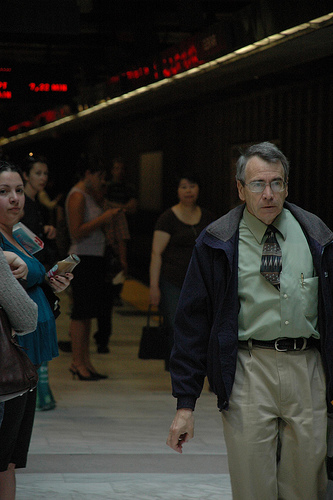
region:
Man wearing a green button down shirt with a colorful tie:
[178, 139, 330, 499]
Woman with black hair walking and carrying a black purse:
[137, 168, 201, 364]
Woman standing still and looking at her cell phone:
[62, 152, 129, 363]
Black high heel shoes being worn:
[63, 352, 112, 394]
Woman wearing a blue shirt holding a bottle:
[0, 158, 84, 365]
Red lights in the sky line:
[15, 41, 199, 93]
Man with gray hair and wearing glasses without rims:
[231, 144, 299, 216]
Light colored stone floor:
[62, 380, 168, 492]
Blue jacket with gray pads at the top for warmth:
[171, 207, 244, 442]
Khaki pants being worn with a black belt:
[231, 333, 318, 499]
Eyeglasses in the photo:
[246, 178, 285, 194]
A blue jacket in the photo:
[192, 251, 236, 352]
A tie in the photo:
[256, 231, 288, 289]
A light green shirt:
[236, 242, 319, 331]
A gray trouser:
[230, 365, 322, 496]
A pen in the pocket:
[298, 269, 307, 287]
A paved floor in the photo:
[47, 412, 149, 480]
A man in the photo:
[167, 182, 331, 498]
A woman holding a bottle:
[0, 159, 82, 382]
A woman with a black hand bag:
[134, 174, 222, 363]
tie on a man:
[257, 224, 285, 301]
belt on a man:
[241, 335, 322, 354]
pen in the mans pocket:
[294, 270, 310, 297]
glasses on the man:
[242, 176, 291, 196]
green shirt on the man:
[235, 206, 322, 352]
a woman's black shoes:
[68, 360, 109, 384]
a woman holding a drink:
[46, 250, 84, 290]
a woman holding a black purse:
[135, 297, 178, 368]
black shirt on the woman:
[151, 202, 210, 299]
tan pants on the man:
[219, 344, 327, 498]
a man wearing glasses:
[219, 161, 325, 224]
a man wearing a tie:
[215, 138, 331, 303]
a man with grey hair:
[207, 113, 300, 249]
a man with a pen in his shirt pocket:
[219, 140, 332, 306]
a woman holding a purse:
[118, 170, 211, 371]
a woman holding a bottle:
[3, 163, 94, 301]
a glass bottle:
[31, 241, 106, 319]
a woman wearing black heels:
[45, 159, 117, 387]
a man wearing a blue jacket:
[157, 149, 329, 395]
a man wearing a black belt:
[211, 146, 322, 361]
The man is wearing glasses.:
[220, 132, 299, 226]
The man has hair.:
[230, 135, 295, 226]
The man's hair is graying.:
[226, 139, 298, 233]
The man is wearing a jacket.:
[159, 135, 332, 451]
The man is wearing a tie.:
[163, 138, 332, 354]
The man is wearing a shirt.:
[161, 138, 332, 458]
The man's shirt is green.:
[166, 132, 332, 448]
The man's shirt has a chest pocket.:
[153, 135, 331, 448]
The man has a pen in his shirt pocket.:
[192, 139, 332, 349]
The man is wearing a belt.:
[170, 138, 332, 416]